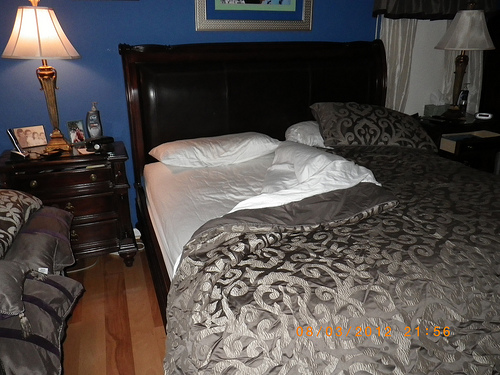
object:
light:
[0, 0, 100, 151]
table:
[1, 135, 137, 270]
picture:
[9, 125, 51, 148]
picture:
[66, 119, 89, 147]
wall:
[1, 0, 446, 231]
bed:
[115, 32, 500, 374]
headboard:
[116, 38, 395, 174]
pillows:
[142, 128, 284, 170]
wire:
[56, 240, 150, 278]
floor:
[50, 230, 183, 374]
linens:
[139, 123, 376, 282]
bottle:
[83, 97, 106, 141]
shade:
[1, 0, 93, 69]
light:
[425, 0, 500, 131]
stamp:
[296, 323, 452, 340]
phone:
[81, 129, 119, 160]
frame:
[193, 0, 317, 34]